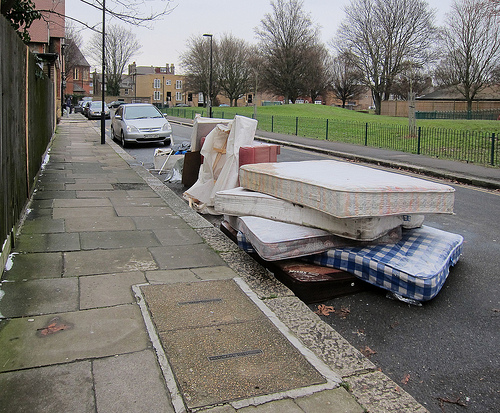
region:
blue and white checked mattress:
[327, 225, 467, 303]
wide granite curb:
[107, 142, 432, 408]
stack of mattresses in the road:
[217, 146, 468, 309]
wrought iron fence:
[164, 107, 496, 164]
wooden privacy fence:
[1, 13, 53, 223]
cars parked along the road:
[79, 91, 174, 145]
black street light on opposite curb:
[197, 30, 219, 122]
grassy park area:
[207, 95, 497, 153]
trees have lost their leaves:
[179, 0, 499, 96]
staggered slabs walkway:
[1, 105, 180, 412]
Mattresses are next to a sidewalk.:
[201, 147, 478, 320]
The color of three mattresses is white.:
[195, 135, 464, 263]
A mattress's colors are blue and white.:
[292, 214, 472, 314]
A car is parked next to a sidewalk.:
[103, 98, 180, 152]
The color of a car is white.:
[108, 92, 175, 151]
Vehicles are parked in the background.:
[70, 91, 115, 123]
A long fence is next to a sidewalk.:
[151, 103, 498, 170]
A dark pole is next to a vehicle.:
[85, 1, 125, 149]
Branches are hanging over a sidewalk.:
[1, 0, 186, 79]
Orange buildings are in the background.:
[110, 56, 499, 125]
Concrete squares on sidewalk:
[55, 183, 135, 264]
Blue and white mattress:
[328, 220, 473, 306]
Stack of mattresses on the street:
[193, 150, 476, 320]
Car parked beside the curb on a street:
[102, 100, 172, 145]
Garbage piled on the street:
[138, 110, 466, 330]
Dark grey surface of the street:
[440, 322, 486, 369]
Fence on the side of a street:
[285, 107, 493, 169]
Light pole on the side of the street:
[198, 25, 221, 117]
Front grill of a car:
[117, 115, 172, 142]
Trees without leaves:
[338, 1, 498, 113]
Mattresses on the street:
[213, 125, 467, 307]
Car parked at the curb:
[107, 98, 178, 151]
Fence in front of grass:
[272, 113, 498, 166]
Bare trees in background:
[193, 40, 498, 117]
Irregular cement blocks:
[35, 152, 152, 390]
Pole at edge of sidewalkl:
[90, 40, 112, 150]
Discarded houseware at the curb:
[147, 108, 470, 329]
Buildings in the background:
[62, 46, 498, 108]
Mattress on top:
[236, 153, 459, 220]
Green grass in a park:
[253, 102, 498, 140]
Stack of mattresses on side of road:
[205, 100, 497, 333]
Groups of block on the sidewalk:
[60, 145, 158, 297]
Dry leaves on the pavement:
[317, 292, 409, 362]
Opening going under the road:
[137, 267, 324, 411]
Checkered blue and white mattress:
[345, 242, 447, 308]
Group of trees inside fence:
[287, 60, 497, 90]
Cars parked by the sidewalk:
[71, 85, 174, 165]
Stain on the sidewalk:
[17, 296, 98, 354]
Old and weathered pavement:
[273, 292, 379, 397]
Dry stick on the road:
[420, 389, 496, 405]